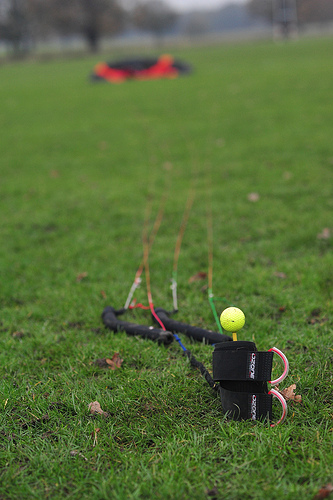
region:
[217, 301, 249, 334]
the ball is color green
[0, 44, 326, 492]
a field is cover with green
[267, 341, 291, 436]
red and white handles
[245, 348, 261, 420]
white letters on black surface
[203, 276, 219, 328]
a green strap on the grass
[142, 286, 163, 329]
a red strap on the grass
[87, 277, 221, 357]
a black thick chord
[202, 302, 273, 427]
the cuff is black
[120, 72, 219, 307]
strings on the grass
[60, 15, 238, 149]
kite on the grass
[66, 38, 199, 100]
the kite is red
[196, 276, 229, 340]
green trim on string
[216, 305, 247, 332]
Small round green ball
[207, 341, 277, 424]
Large black cloth harness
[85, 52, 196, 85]
Large black and orange kite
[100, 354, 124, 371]
Small brown dead leaf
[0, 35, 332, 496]
Large open grassy field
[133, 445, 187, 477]
Short tuft of green grass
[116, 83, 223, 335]
Long colored thin lines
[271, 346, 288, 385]
Short round red handles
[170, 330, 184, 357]
Thin blue cloth line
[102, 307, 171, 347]
Long large black strap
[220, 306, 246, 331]
a yellow golf ball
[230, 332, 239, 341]
a yellow tee holding a golf ball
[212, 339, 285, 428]
black parachute grips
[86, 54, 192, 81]
red and black parachute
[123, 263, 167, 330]
red rope for parachute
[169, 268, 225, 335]
green rope on parachute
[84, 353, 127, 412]
leaves in the grass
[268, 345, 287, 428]
red hand grips for parachute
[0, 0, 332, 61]
out of focus in background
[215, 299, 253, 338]
golf ball is yellow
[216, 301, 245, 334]
golf ball is yellow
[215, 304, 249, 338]
golf ball is yellow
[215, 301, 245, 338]
golf ball is yellow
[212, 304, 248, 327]
golf ball is yellow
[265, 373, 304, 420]
dry leaf on the grass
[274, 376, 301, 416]
dry leaf on the grass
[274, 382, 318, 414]
dry leaf on the grass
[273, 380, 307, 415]
dry leaf on the grass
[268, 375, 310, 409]
dry leaf on the grass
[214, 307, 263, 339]
The golf ball is the shape of a circle.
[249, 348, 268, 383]
The brand name on the other stirrups.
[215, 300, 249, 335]
the ball is green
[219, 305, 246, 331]
green golf ball on a stick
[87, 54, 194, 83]
red and black object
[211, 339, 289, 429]
black handle with pink strings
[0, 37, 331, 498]
green grass with dead leaves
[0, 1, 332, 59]
trees next to the field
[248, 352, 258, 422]
white writing on the black handles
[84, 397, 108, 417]
dead leaf lying in grass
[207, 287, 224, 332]
green string attached to a harness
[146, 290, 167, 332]
pink string attached to a harness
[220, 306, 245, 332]
small yellow golf ball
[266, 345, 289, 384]
red and white plastic handle grip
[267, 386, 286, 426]
red and white plastic handle grip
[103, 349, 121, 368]
brown leaf in the green grass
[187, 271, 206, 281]
brown leaf in the green grass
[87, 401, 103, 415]
brown leaf in the green grass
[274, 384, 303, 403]
brown leaf in the green grass